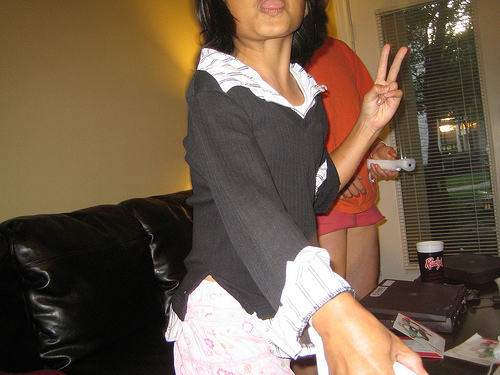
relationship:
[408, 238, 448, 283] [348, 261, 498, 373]
coffee cup on table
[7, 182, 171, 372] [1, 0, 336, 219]
couch next to wall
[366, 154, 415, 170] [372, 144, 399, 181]
control in hand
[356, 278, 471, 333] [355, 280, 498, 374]
briefcase on table